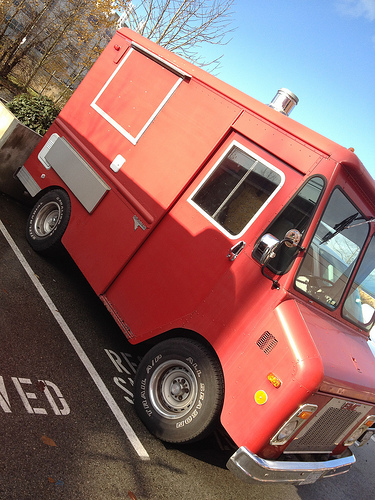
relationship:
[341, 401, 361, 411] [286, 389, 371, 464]
logo front grill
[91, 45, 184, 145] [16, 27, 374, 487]
white trim on parked truck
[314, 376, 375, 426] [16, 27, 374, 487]
logo on parked truck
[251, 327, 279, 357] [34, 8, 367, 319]
hole on vehicle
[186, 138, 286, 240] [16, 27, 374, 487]
window on parked truck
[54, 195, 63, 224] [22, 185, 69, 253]
white writing on black tire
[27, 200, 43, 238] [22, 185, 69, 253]
white writing on black tire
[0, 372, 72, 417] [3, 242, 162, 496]
writing on ground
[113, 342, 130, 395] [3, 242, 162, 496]
writing on ground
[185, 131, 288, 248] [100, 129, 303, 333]
panels on door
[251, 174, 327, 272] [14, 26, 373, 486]
triangular panel on truck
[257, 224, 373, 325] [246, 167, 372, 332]
car behind windows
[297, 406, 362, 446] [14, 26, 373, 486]
front grill on truck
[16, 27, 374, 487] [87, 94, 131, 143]
parked truck with trim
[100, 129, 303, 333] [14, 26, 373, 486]
door on truck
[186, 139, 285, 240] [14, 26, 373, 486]
window on truck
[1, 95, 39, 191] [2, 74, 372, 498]
planter by parking lot